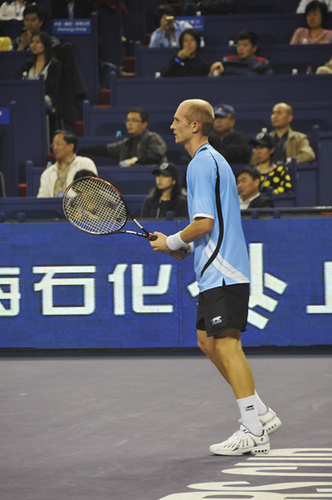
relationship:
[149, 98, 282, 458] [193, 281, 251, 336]
man wearing shorts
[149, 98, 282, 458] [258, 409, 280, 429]
man wearing sneakers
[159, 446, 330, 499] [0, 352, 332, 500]
white writing painted onto court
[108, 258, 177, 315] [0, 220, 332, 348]
writing painted onto blue wall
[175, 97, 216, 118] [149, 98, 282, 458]
bald head of man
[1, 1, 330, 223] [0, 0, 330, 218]
stand of people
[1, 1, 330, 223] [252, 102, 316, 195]
stand of people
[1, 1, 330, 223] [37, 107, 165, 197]
stand of people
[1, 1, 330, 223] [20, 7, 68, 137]
stand of people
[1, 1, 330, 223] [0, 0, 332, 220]
stand of man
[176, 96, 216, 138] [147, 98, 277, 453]
hair of man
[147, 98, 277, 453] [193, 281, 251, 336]
man wearing shorts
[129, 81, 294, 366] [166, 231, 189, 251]
man wearing band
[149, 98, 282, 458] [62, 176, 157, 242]
man holding racket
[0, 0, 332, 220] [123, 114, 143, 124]
man wearing glasses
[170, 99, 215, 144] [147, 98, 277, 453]
bald head of man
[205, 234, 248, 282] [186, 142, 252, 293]
stripes on jersey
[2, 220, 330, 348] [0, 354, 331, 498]
blue wall on court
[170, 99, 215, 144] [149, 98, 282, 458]
bald head of man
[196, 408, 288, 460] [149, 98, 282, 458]
shoes of man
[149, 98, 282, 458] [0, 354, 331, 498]
man on court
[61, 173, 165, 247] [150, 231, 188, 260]
racket in hand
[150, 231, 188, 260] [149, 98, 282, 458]
hand of man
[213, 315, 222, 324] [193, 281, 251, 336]
logo on shorts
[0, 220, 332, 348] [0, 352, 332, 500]
blue wall near court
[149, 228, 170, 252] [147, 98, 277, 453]
hand on man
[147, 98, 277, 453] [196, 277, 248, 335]
man wearing shorts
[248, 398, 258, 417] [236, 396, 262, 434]
logo on sock